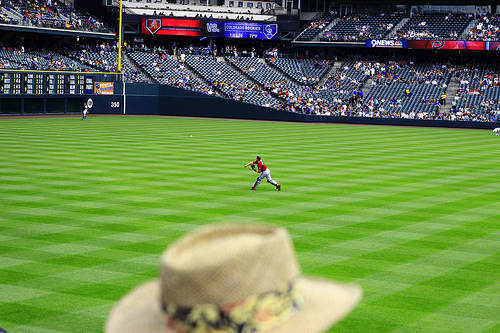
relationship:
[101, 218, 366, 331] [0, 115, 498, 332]
hat in front of field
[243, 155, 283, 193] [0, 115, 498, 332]
catcher on field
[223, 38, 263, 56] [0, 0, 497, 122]
box in stand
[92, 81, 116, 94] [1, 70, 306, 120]
sign on wall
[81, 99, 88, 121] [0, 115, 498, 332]
outfielder on field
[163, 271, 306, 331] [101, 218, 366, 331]
band on hat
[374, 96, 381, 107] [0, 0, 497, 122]
spectator in stand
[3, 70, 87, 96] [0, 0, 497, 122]
scoreboard on stand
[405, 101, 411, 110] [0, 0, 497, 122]
seat in stand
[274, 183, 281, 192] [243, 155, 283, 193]
cleat on catcher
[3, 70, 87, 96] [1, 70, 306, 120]
scoreboard on wall